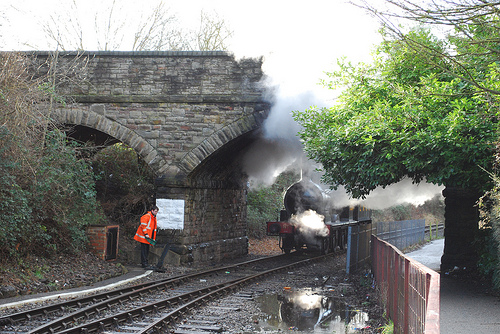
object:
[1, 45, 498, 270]
bridge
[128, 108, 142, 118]
brick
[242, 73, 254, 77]
brick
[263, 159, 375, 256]
train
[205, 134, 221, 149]
brick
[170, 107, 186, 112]
brick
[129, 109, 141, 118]
brick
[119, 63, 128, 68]
brick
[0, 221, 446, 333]
train tracks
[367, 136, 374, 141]
green leaves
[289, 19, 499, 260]
tree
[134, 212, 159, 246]
jacket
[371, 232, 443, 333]
fence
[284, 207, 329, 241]
steam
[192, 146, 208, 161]
brick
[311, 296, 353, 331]
reflection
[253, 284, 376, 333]
water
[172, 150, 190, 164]
grey brick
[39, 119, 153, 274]
archway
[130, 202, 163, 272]
man